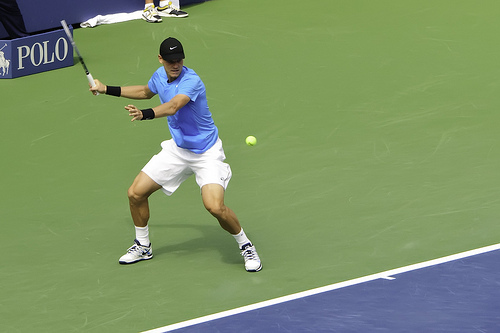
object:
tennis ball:
[244, 134, 258, 147]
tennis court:
[1, 0, 499, 333]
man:
[88, 36, 263, 273]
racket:
[62, 19, 100, 95]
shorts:
[141, 133, 232, 195]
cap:
[159, 36, 185, 63]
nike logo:
[168, 44, 179, 51]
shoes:
[228, 238, 259, 272]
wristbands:
[105, 84, 155, 120]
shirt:
[146, 65, 218, 156]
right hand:
[86, 78, 107, 97]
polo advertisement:
[16, 37, 69, 74]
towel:
[79, 7, 145, 28]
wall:
[1, 1, 204, 39]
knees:
[126, 186, 225, 216]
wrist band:
[139, 108, 156, 121]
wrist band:
[104, 84, 122, 97]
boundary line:
[132, 240, 499, 332]